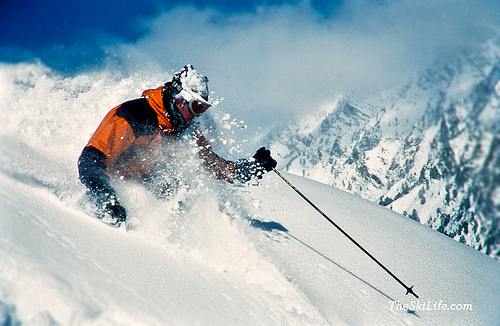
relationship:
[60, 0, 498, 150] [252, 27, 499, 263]
fog hanging above mountain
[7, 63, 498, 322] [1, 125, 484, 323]
snow covering mountain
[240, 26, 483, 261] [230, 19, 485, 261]
snow covering mountain